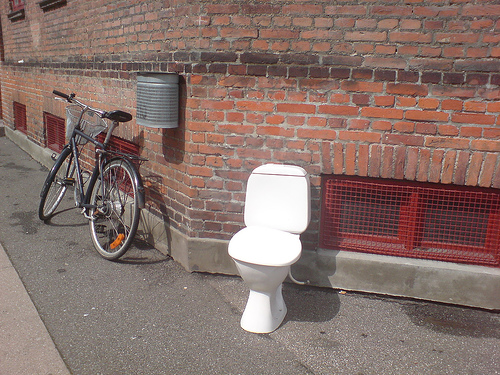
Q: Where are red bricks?
A: On side of building.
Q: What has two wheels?
A: Bicycle.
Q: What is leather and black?
A: Bicycle seat.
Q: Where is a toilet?
A: Against the building.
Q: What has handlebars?
A: The bicycle.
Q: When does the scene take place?
A: During daytime.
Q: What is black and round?
A: Wheels.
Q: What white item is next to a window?
A: A toilet.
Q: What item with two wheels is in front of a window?
A: A bicycle.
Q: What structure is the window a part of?
A: The building.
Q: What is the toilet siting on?
A: The sidewalk.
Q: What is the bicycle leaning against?
A: The building.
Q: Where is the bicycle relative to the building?
A: Leaning against it.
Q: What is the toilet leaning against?
A: The building.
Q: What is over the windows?
A: Window covers.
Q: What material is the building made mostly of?
A: Brick.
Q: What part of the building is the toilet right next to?
A: The window.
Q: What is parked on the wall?
A: A bicycle.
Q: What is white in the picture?
A: A toilet.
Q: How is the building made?
A: Of brick.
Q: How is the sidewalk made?
A: Of concrete.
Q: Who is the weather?
A: Sunny and clear.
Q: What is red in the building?
A: Grates.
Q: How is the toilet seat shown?
A: Closed.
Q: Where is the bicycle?
A: Against the wall.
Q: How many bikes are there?
A: 1.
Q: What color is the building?
A: Brick red.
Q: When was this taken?
A: Daytime.